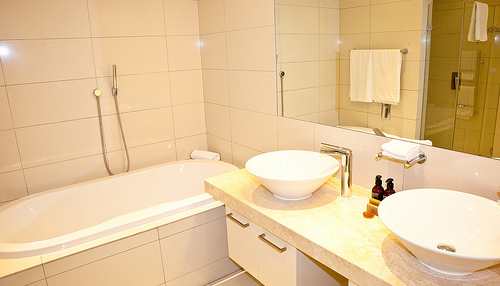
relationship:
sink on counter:
[244, 148, 341, 202] [204, 167, 499, 285]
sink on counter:
[377, 187, 498, 274] [204, 167, 499, 285]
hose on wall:
[93, 64, 131, 175] [1, 1, 202, 185]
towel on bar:
[349, 48, 402, 105] [348, 47, 410, 55]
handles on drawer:
[227, 209, 287, 253] [225, 203, 297, 285]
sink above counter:
[244, 148, 341, 202] [204, 167, 499, 285]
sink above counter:
[377, 187, 498, 274] [204, 167, 499, 285]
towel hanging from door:
[466, 1, 490, 45] [454, 1, 493, 156]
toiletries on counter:
[362, 174, 395, 222] [204, 167, 499, 285]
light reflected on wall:
[0, 42, 18, 65] [1, 1, 202, 185]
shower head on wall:
[110, 63, 121, 97] [1, 1, 202, 185]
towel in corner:
[190, 148, 220, 162] [164, 2, 231, 166]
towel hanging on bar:
[349, 48, 402, 105] [348, 47, 410, 55]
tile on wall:
[89, 34, 171, 78] [1, 1, 202, 185]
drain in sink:
[437, 240, 456, 254] [377, 187, 498, 274]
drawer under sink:
[225, 203, 297, 285] [244, 148, 341, 202]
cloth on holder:
[459, 48, 481, 72] [459, 48, 482, 58]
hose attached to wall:
[93, 64, 131, 175] [1, 1, 202, 185]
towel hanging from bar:
[349, 48, 402, 105] [348, 47, 410, 55]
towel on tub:
[190, 148, 220, 162] [0, 158, 244, 284]